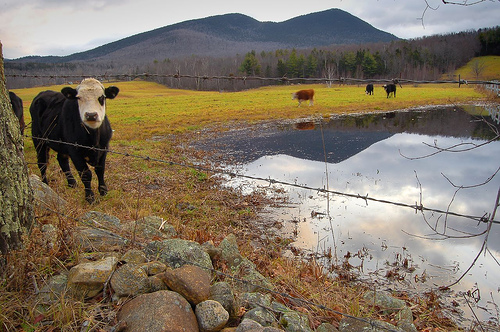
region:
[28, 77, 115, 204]
black and white cow in fore front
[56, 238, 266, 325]
rocks on the ground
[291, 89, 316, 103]
brown cow far away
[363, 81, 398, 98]
black cows in the distance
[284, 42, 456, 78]
trees and woods in background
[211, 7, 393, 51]
mountain peaks in background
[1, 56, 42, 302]
tree trunk on edge of picture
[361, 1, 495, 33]
cloudy overcast sky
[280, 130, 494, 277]
water pond near cows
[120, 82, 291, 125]
green and yellowish grass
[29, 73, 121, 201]
Black and white cow looking towards camera.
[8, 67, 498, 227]
Barbed wire fence.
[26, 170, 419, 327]
Rocks of varying sizes and colors.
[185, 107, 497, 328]
Pond with debris floating in it.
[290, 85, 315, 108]
Brown cow.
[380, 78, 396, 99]
Mostly black cow.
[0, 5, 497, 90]
Rolling hills with evergreen and desiduous trees in front of them.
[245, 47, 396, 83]
Evergreen trees.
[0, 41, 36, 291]
Tree trunk with peeling bark.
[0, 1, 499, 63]
Cloudy sky.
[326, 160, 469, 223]
REFLECTION OF CLOUDS IN POND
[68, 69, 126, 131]
COW WITH ONE BLACK EYE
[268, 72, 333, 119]
BROWN COW IN THE DISTANCE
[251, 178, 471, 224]
BARBED WIRE FENCING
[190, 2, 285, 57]
MOUNTAIN RIDGE IN THE DISTANCE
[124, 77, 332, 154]
YELLOW GREEN GRASS FOR COW GRAZING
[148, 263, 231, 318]
BROWN ROCKS WITH LICHENS ATTACHED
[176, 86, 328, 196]
SHALLOW POND FOR COWS TO DRINK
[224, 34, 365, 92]
EVERGREEN TREES IN THE DISTANCE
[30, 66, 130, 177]
BLACK COW WITH WHITE FACE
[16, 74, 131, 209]
Cow looking at picture taker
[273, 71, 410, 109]
Three cows walking in pasture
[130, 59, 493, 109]
Bobbed wire fencing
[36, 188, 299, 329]
Rocks piled up next to tree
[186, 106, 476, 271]
Natural pond in open country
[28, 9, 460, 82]
Mountains in distant background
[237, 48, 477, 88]
Tree in background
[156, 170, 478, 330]
Old and fallen leaves and grass in pond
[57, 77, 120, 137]
Cows tan face with black body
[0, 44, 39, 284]
Bark on side of tree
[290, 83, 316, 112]
a brown and white cow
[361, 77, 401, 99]
two black cows in a pasture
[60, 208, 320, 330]
a cluster of boulders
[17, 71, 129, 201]
a black cow with a white face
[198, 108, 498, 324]
a body of water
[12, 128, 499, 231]
a barb wired fence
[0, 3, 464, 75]
mountains in the background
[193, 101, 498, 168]
the mountain's reflection in the water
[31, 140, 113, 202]
four black cow legs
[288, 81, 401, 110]
one brown cow and two black cows